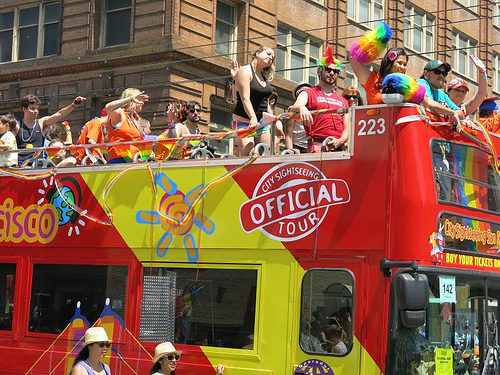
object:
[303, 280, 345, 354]
reflection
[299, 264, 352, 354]
window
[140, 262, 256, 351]
window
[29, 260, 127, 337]
window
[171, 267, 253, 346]
reflection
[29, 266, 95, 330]
reflection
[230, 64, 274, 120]
black top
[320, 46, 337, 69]
mohawk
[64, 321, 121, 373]
woman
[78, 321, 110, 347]
fedora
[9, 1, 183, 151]
wall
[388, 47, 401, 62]
flower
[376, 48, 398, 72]
hair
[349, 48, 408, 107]
woman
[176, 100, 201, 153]
man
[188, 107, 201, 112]
sunglasses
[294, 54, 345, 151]
man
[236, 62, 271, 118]
tank top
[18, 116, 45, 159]
tank top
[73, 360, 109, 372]
tank top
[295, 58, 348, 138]
man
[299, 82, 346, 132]
t shirt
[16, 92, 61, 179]
man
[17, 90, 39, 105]
black hair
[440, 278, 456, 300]
number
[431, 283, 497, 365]
window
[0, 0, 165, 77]
building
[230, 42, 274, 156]
woman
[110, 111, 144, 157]
tank top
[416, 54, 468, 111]
man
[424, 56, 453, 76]
hat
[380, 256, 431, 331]
mirror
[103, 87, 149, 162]
woman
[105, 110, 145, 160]
orange t-shirt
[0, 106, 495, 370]
bus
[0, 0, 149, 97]
building